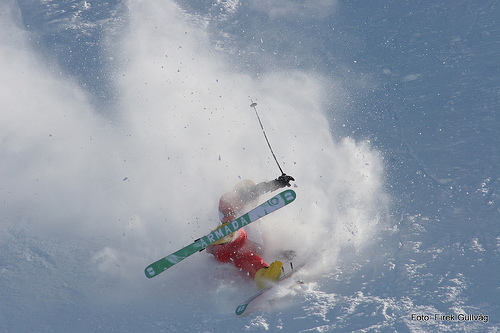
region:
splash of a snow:
[36, 165, 80, 207]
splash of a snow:
[63, 176, 102, 239]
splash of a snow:
[77, 250, 122, 285]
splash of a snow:
[307, 202, 353, 247]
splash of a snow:
[206, 75, 228, 120]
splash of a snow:
[264, 75, 285, 90]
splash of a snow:
[159, 9, 213, 45]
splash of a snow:
[52, 71, 84, 83]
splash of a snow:
[303, 201, 339, 228]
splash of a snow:
[178, 154, 204, 186]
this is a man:
[172, 197, 270, 273]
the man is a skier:
[150, 224, 325, 311]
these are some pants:
[246, 257, 259, 269]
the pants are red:
[235, 237, 252, 270]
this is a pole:
[235, 145, 337, 193]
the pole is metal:
[229, 104, 323, 168]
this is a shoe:
[240, 261, 275, 269]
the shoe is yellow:
[246, 259, 290, 296]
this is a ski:
[163, 255, 172, 269]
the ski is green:
[155, 185, 223, 262]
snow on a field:
[416, 97, 443, 157]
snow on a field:
[446, 171, 454, 220]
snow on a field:
[430, 240, 457, 271]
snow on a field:
[399, 278, 435, 286]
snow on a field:
[358, 283, 384, 317]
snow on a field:
[346, 36, 393, 104]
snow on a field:
[55, 30, 95, 70]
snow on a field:
[302, 298, 337, 323]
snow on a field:
[260, 303, 287, 329]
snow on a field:
[476, 299, 498, 314]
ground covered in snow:
[275, 70, 496, 261]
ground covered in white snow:
[243, 75, 438, 305]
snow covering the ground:
[354, 154, 476, 318]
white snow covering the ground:
[339, 129, 485, 304]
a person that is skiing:
[157, 95, 392, 318]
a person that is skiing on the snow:
[191, 124, 353, 307]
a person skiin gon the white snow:
[158, 121, 463, 328]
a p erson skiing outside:
[171, 71, 416, 325]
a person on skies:
[108, 111, 413, 328]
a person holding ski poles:
[71, 33, 390, 316]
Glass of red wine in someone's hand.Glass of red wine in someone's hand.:
[6, 156, 85, 163]